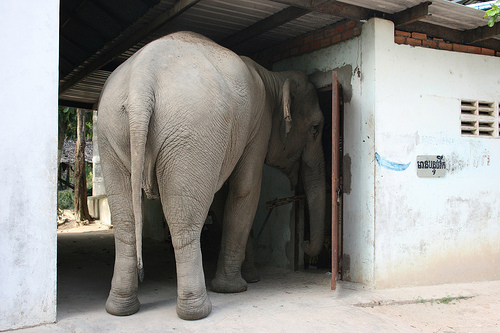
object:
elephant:
[97, 31, 324, 320]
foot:
[175, 298, 212, 319]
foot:
[103, 299, 142, 315]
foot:
[207, 279, 248, 295]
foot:
[240, 270, 260, 283]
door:
[330, 69, 338, 290]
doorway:
[298, 69, 340, 277]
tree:
[71, 108, 93, 225]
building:
[59, 2, 499, 286]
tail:
[127, 90, 156, 284]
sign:
[414, 155, 447, 179]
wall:
[373, 19, 497, 288]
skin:
[97, 30, 328, 320]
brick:
[394, 28, 411, 38]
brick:
[410, 32, 426, 40]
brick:
[405, 38, 420, 48]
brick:
[421, 38, 436, 47]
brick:
[437, 42, 453, 51]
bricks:
[394, 37, 406, 46]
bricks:
[276, 48, 299, 59]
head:
[276, 70, 328, 258]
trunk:
[300, 149, 328, 256]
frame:
[218, 0, 427, 47]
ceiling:
[60, 0, 490, 113]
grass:
[85, 169, 92, 189]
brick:
[453, 44, 467, 54]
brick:
[469, 45, 482, 53]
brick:
[481, 49, 494, 56]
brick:
[340, 27, 362, 40]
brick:
[327, 34, 343, 45]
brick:
[343, 19, 359, 27]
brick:
[327, 21, 346, 35]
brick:
[302, 30, 323, 41]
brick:
[309, 39, 333, 49]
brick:
[287, 47, 303, 58]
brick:
[263, 44, 286, 51]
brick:
[250, 53, 266, 63]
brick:
[395, 36, 405, 43]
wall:
[273, 20, 376, 285]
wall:
[253, 163, 302, 268]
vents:
[459, 128, 497, 139]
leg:
[156, 157, 219, 321]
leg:
[101, 158, 144, 315]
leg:
[244, 232, 261, 281]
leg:
[210, 166, 263, 293]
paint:
[374, 151, 411, 172]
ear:
[277, 78, 297, 138]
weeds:
[55, 190, 77, 208]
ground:
[57, 205, 107, 233]